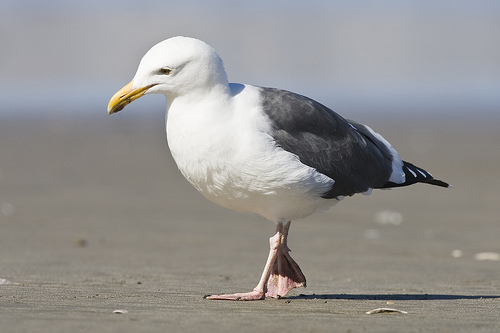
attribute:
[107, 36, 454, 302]
bird — standing, white, gray, black, seagull, adult, herring gull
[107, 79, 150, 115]
beak — yellow, short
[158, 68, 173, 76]
eye — light colored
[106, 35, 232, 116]
head — white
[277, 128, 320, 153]
feather — gray, white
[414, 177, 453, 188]
tail feather — black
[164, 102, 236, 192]
chest — white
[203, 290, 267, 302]
foot — orange, webbed, pink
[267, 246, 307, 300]
foot — orange, webbed, pink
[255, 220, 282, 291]
leg — orange, pink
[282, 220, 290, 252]
leg — orange, pink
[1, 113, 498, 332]
sand — bare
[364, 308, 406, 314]
shell — broken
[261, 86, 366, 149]
wing — black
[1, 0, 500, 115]
sky — gray